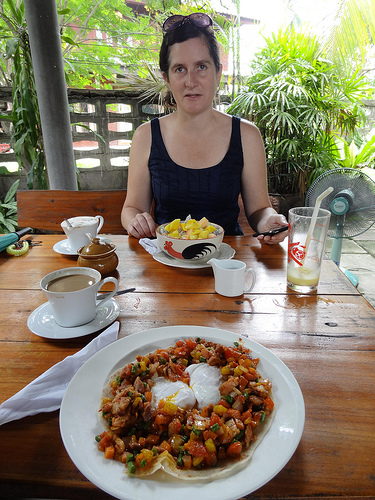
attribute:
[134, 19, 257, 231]
woman — sitting, eating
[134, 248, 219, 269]
plate — white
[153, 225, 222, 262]
bowl — small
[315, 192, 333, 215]
straw — white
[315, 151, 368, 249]
fan — blue, green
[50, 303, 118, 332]
cup — white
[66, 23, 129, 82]
plants — green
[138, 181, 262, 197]
shirt — black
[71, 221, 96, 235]
sour cream — dollops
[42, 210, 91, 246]
pitcher — white, small